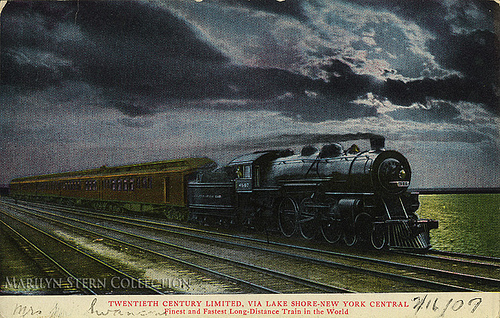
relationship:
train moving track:
[8, 131, 442, 256] [49, 218, 222, 280]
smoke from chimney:
[236, 131, 371, 146] [366, 133, 384, 150]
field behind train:
[419, 190, 498, 257] [8, 131, 442, 256]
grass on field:
[414, 190, 498, 260] [419, 190, 498, 257]